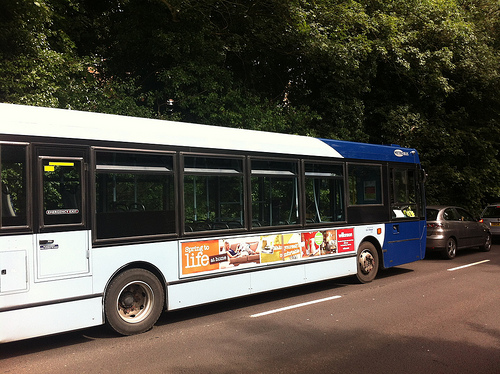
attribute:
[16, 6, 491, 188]
leaves — green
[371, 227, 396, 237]
reflector bus — orange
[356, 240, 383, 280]
rubber tire — round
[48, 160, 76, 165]
sticker — yellow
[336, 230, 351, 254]
writing — white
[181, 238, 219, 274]
sign — orange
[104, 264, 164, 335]
wheel — white, rust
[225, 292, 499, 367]
road — black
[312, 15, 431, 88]
leaves — lush, green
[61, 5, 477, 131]
trees — mature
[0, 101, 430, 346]
bus — is white, is blue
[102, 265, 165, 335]
tire — round, rubber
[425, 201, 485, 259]
vehicles — driving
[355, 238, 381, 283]
tire — round, rubber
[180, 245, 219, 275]
lettering — white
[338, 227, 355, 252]
sign — red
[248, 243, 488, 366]
stripes — white